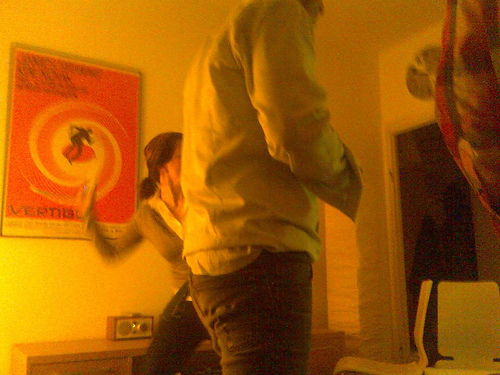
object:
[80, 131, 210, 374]
woman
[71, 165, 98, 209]
remote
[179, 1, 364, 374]
man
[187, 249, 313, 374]
jeans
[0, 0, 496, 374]
wall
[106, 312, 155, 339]
radio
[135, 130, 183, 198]
hair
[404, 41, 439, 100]
clock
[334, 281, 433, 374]
chair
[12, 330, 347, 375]
cabinet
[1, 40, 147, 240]
poster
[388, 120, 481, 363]
door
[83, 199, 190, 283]
sweater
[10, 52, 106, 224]
letters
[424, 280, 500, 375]
chair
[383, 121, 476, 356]
frame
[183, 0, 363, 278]
shirt